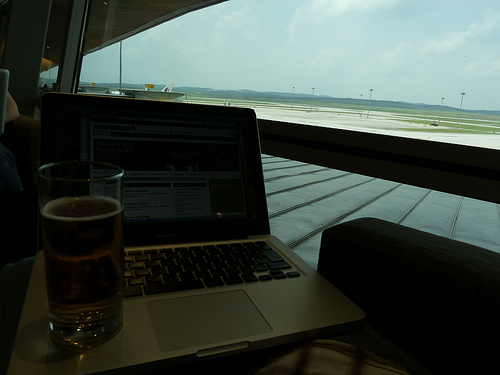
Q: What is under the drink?
A: Laptop.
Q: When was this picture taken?
A: Daytime.